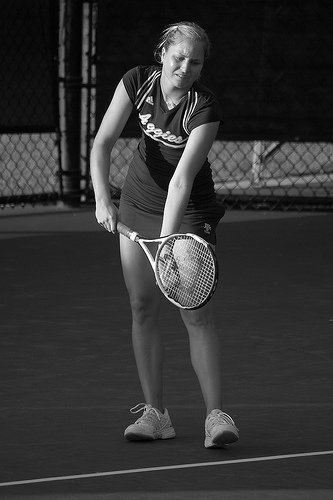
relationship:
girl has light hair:
[90, 20, 248, 453] [151, 20, 213, 61]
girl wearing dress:
[87, 20, 242, 452] [117, 66, 217, 246]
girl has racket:
[87, 20, 242, 452] [107, 214, 219, 310]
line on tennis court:
[0, 450, 331, 486] [6, 180, 330, 497]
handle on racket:
[93, 209, 140, 241] [111, 222, 220, 309]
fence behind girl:
[0, 1, 331, 213] [87, 20, 242, 452]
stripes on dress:
[135, 66, 201, 134] [110, 62, 229, 247]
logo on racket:
[165, 249, 203, 291] [111, 222, 220, 309]